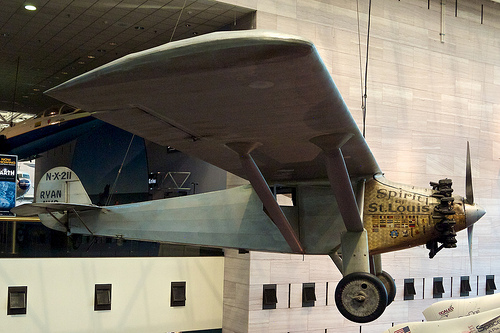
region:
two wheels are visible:
[336, 236, 392, 320]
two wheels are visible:
[317, 223, 411, 325]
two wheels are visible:
[326, 266, 418, 330]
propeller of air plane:
[459, 138, 486, 281]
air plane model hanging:
[9, 31, 499, 325]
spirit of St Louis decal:
[364, 187, 442, 214]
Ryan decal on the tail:
[36, 187, 63, 199]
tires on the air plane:
[331, 265, 399, 324]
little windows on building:
[2, 275, 194, 320]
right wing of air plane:
[36, 25, 379, 185]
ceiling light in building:
[15, 2, 41, 17]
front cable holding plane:
[359, 0, 374, 132]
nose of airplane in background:
[16, 168, 31, 196]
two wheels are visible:
[340, 262, 397, 304]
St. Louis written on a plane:
[368, 200, 435, 217]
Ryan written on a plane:
[40, 188, 62, 199]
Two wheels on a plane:
[333, 269, 400, 319]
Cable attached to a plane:
[352, 12, 377, 137]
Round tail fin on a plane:
[31, 166, 91, 204]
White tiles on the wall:
[378, 40, 485, 136]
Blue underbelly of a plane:
[7, 112, 117, 149]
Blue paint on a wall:
[72, 144, 149, 195]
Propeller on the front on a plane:
[462, 136, 485, 276]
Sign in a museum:
[1, 152, 17, 214]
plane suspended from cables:
[36, 16, 487, 323]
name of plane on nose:
[365, 184, 437, 224]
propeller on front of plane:
[447, 138, 491, 286]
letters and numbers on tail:
[31, 163, 80, 209]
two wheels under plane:
[327, 266, 408, 323]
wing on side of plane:
[64, 18, 376, 200]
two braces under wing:
[230, 125, 367, 241]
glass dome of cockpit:
[31, 97, 82, 126]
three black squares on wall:
[0, 278, 200, 323]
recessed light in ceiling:
[18, 1, 45, 21]